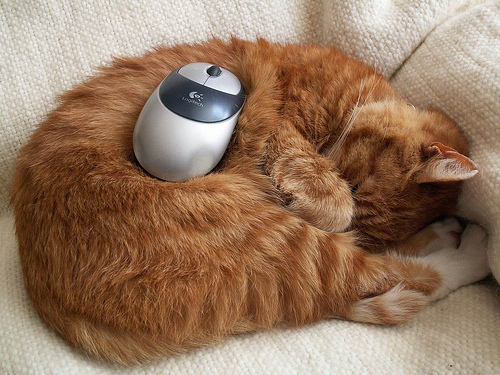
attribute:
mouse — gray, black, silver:
[133, 61, 243, 181]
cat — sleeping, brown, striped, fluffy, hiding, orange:
[17, 37, 490, 362]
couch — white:
[0, 1, 497, 374]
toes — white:
[429, 218, 488, 280]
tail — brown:
[24, 257, 181, 365]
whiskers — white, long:
[332, 64, 383, 157]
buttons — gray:
[181, 61, 240, 93]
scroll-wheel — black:
[208, 64, 221, 76]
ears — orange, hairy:
[424, 145, 478, 183]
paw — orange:
[280, 138, 354, 229]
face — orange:
[340, 130, 416, 235]